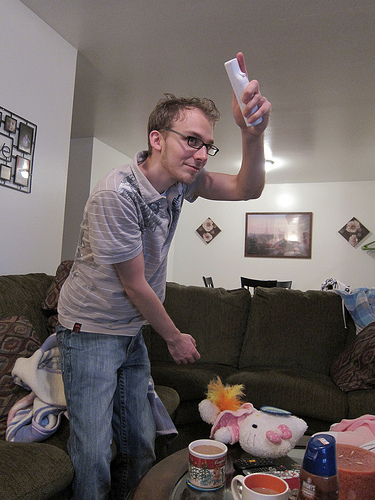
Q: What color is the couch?
A: Greenish gray.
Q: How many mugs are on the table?
A: Two.